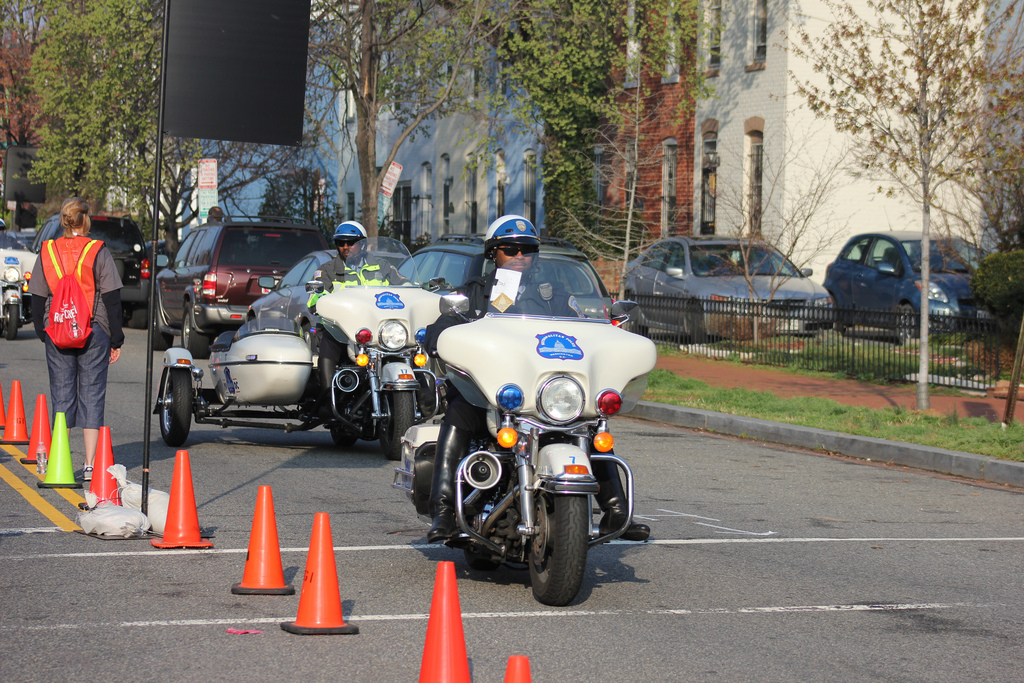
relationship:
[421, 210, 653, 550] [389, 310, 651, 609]
cop riding bike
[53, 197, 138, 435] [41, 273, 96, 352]
woman wearing backpack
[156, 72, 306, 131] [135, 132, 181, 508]
sign on pole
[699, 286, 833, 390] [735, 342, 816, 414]
fence next to sidewalk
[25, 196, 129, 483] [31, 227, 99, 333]
woman wearing vest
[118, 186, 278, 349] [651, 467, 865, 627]
suv driving down street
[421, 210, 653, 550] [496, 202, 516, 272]
cop wearing helmet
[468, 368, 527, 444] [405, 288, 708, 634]
light on bike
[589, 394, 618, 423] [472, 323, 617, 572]
light on bike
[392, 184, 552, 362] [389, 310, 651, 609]
cop on bike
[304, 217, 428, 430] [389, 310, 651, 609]
cop on bike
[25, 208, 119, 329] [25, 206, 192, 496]
vest on woman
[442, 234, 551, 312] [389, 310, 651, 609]
cop on bike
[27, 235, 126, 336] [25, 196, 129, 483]
vest on woman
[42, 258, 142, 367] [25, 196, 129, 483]
backpack on woman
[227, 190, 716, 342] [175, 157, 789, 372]
cars on streetside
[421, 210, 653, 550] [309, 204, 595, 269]
cop wearing helmets